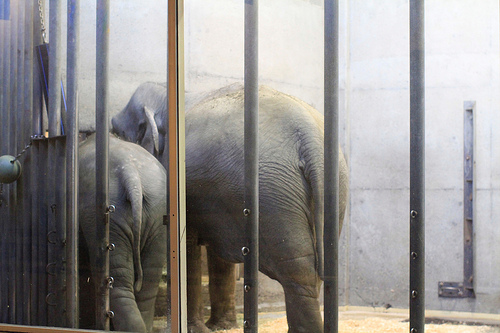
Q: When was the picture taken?
A: Daytime.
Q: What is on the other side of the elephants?
A: Wall.